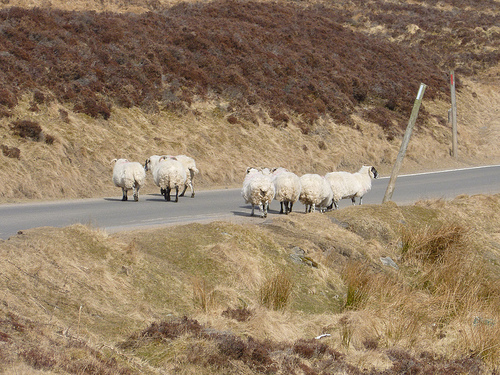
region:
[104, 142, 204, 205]
The group of sheep on the left.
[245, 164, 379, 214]
The group of sheep on the right.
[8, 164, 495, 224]
The street where the sheep are standing.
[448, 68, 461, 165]
The gray pole on the left.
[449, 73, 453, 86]
The red paint on the gray pole.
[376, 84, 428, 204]
The gray pole on the right.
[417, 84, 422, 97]
The white paint on the gray pole.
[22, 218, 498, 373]
The grass area on the left.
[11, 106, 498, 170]
The tan grass on the right.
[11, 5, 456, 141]
The dark brown grass area.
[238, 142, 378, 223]
Four sheep crossing the road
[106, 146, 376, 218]
Small group of sheep crossing the road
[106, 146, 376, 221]
Seven sheep on a road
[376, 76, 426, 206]
Crooked wood pole beside road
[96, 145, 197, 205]
Three sheep walking together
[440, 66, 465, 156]
Metal pole with a red sticker at top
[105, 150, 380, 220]
Sheep with black heads and feet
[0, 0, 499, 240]
Sheep on a mountain road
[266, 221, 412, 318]
a rocky landscape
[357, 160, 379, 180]
Side of a sheep's head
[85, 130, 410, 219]
sheep are crossing the street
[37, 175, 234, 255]
the road is paved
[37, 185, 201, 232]
the road is paved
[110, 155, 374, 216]
flock of sheep crossing road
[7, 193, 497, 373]
dry grassy field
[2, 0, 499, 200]
hill with dry grass and sage brush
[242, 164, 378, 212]
group of four white sheep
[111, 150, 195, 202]
group of three sheep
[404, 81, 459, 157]
two wooden posts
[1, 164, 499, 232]
asphalt country road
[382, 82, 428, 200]
wooden post by roadside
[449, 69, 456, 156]
wooden post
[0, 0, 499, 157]
red sagebrush across hill